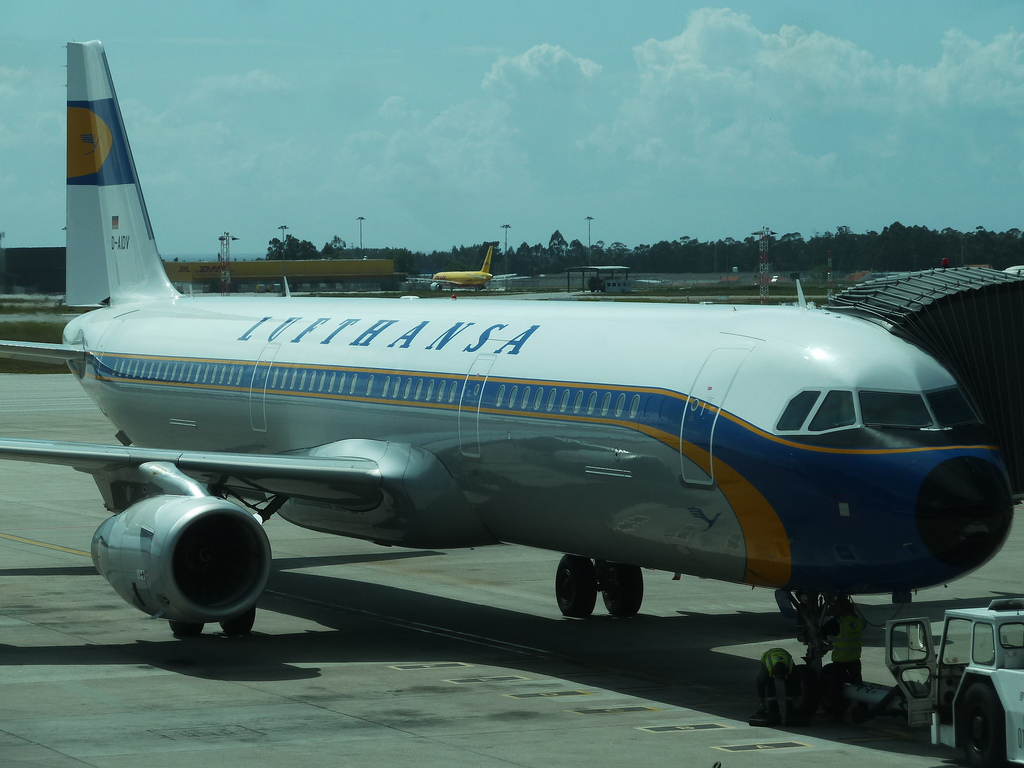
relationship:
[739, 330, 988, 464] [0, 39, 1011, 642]
windows on airplane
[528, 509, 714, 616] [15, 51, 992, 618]
wheels on plane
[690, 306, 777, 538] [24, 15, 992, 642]
door on plane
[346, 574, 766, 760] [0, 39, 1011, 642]
shadow of airplane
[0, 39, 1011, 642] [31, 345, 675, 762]
airplane across runway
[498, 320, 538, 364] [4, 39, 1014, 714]
letter on airplane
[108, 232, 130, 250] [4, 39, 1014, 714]
letter on airplane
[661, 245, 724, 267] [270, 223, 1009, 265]
tree on woods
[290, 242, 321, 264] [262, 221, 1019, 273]
tree in woods